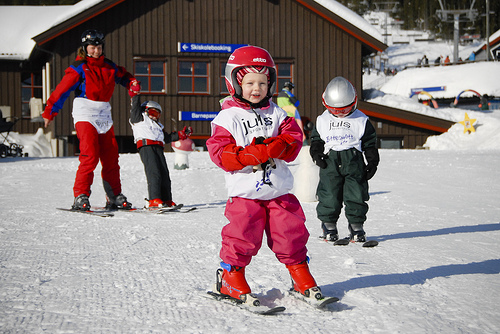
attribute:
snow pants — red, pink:
[218, 192, 311, 265]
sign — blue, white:
[177, 41, 250, 53]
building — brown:
[1, 0, 459, 157]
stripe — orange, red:
[36, 1, 382, 54]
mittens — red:
[222, 132, 298, 172]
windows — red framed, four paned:
[133, 61, 295, 96]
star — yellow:
[457, 114, 477, 134]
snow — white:
[0, 1, 499, 333]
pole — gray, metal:
[453, 15, 460, 65]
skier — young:
[309, 77, 380, 248]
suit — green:
[309, 108, 381, 234]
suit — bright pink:
[205, 96, 310, 266]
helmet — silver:
[321, 76, 358, 119]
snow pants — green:
[315, 146, 370, 224]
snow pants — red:
[74, 121, 123, 197]